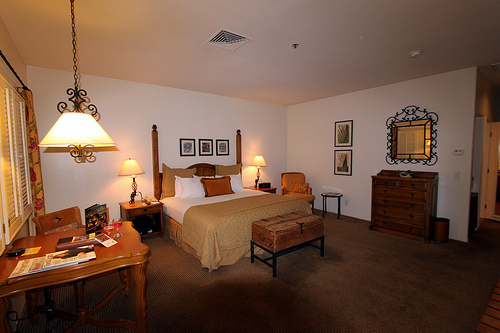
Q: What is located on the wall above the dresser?
A: A mirror.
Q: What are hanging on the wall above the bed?
A: Pictures.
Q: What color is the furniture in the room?
A: Brown.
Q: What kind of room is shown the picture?
A: A bedroom.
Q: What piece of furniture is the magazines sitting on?
A: A table.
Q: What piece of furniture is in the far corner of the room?
A: A chair.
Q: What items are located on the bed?
A: Pillows.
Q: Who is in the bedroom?
A: No one.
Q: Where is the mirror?
A: Above the dresser.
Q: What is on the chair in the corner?
A: A pillow.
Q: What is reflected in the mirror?
A: Light.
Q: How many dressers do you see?
A: One.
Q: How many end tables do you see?
A: Two.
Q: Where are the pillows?
A: On the bed.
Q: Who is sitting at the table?
A: Nobody.